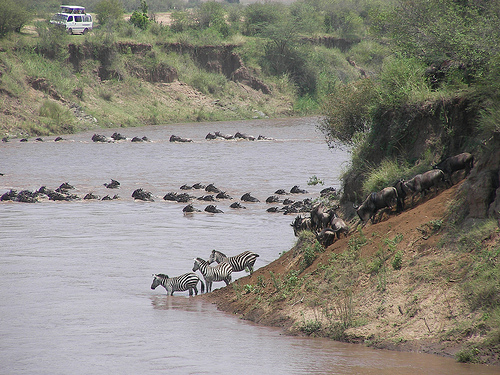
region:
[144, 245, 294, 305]
Three zebras by the water.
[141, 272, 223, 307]
A zebra walking in to water.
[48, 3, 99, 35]
A white van on the road.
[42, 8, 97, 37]
A white can near the water.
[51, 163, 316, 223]
A herd of animals crossing the river.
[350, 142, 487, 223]
Animals walking down the hill side.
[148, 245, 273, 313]
A group of animals on the hillside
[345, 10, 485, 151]
Shrubs on the cliffs edge.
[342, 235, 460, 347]
Some grass growing on the hillside.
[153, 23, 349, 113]
The hillside by the river.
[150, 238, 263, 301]
these are three zebras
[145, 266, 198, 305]
the zebra is in the water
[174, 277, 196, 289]
the zebra is fat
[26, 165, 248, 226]
these are wildbeasts crossing the river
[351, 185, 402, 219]
this is a wildbeast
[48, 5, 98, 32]
this is a van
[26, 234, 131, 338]
the water is calm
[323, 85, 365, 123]
the leaves are green in color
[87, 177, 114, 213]
the wild beast is swimming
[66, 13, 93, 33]
the van is white in color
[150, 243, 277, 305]
three zebras stnading at the bottom of the hill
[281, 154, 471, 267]
several water buffalo walking down a hill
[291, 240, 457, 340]
plants growing on the side of the hill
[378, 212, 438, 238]
brown dirt of the ground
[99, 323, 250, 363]
calm brown water of the river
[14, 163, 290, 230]
many water buffalo in the water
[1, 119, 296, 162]
several water buffalo crossing the river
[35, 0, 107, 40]
two vehicles park in the distance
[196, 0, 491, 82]
several trees growing on the river bank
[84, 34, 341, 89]
dirt cliff face on the river bank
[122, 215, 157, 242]
part of a water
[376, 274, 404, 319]
part of a floor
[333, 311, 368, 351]
dge of a shore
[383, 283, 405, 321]
part of a ground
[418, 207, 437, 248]
part of a ground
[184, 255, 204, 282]
part of a xrnra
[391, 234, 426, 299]
part of a ground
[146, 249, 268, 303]
Zebras at watering hole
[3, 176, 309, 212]
Wildebeest crossing a river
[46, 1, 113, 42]
White van parked on a bluff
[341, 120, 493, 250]
Wildebeests walking downhill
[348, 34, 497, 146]
Shrubs on a bluff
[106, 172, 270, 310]
Wild animals at a river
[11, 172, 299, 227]
animals crossing a river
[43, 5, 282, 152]
White van watching animals cross a river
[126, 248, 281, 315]
3 zebras entering a river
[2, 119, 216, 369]
Muddy river with animals crossing